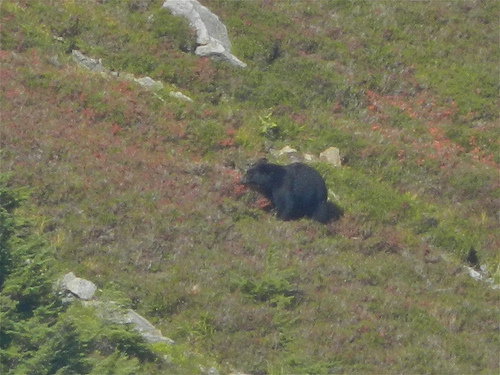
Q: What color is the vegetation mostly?
A: Green.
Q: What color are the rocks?
A: Grey.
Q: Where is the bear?
A: In the grass.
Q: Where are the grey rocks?
A: Above the bear.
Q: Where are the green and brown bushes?
A: On mountainside.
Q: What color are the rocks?
A: Gray.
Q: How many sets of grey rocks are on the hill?
A: Five.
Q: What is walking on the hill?
A: A black bear.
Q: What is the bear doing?
A: Walking.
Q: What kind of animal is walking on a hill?
A: A black bear.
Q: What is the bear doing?
A: Walking.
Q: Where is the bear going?
A: Up a hill.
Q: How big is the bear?
A: Very big.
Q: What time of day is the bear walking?
A: During the afternoon.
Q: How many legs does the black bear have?
A: Four.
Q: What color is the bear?
A: Black.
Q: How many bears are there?
A: 1.